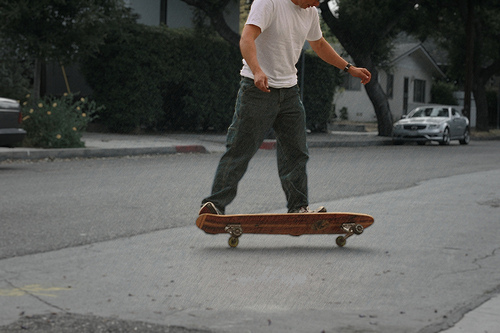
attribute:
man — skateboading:
[198, 1, 373, 216]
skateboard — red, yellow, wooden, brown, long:
[194, 212, 375, 246]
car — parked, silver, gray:
[391, 101, 472, 147]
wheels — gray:
[224, 223, 243, 249]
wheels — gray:
[335, 222, 366, 248]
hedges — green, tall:
[80, 21, 336, 133]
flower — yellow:
[79, 110, 87, 118]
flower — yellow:
[55, 134, 63, 140]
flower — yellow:
[79, 97, 85, 104]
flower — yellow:
[44, 109, 51, 117]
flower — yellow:
[36, 102, 45, 108]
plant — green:
[14, 87, 106, 151]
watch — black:
[341, 61, 355, 76]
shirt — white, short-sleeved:
[237, 0, 325, 89]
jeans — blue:
[199, 76, 310, 211]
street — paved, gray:
[0, 138, 498, 331]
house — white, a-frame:
[326, 40, 447, 128]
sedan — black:
[1, 96, 29, 149]